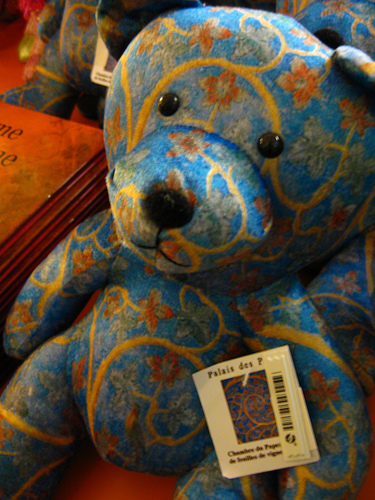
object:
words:
[205, 351, 267, 385]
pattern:
[109, 280, 161, 361]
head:
[99, 0, 375, 273]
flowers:
[107, 111, 126, 160]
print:
[84, 21, 314, 355]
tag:
[189, 346, 322, 476]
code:
[257, 372, 312, 438]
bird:
[147, 49, 209, 160]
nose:
[137, 178, 193, 229]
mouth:
[123, 210, 198, 284]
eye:
[156, 90, 180, 115]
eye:
[256, 128, 283, 160]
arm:
[5, 182, 113, 362]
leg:
[0, 329, 95, 492]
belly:
[101, 292, 188, 402]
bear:
[0, 3, 375, 500]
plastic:
[129, 73, 196, 130]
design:
[95, 296, 203, 450]